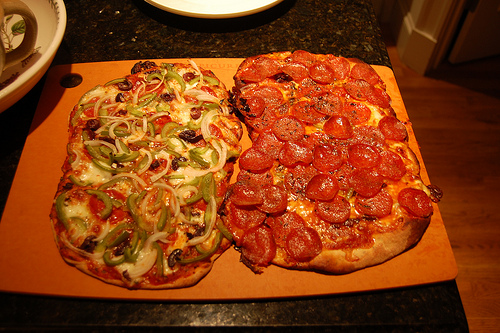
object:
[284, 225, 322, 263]
pepperoni slice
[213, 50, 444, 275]
pizza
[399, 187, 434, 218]
pepperoni slice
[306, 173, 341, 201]
pepperoni slice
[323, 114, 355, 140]
pepperoni slice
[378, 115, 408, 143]
pepperoni slice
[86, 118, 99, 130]
black olive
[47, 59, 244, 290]
pizza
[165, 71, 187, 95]
green pepper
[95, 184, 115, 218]
green pepper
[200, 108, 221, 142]
onion slice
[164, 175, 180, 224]
onion slice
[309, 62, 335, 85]
pepperoni slice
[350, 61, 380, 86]
pepperoni slice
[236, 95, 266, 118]
pepperoni slice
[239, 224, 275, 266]
pepperoni slice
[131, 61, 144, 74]
black olive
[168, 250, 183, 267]
black olive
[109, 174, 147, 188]
onion slice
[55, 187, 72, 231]
green pepper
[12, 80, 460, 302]
tray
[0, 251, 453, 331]
counter top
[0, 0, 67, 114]
bowl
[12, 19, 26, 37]
foliage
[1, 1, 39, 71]
cup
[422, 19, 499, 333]
floor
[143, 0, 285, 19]
plate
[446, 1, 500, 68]
door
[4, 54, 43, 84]
handle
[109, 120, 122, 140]
onion slice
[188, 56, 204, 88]
onion slice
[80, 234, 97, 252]
black olive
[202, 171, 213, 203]
green pepper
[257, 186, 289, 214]
pepperoni slice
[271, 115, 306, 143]
pepperoni slice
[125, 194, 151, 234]
green pepper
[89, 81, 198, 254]
toppings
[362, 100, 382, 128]
cheese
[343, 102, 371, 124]
pepperoni slice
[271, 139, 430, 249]
cheese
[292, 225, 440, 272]
crust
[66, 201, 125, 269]
cheese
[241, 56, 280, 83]
pepperoni slice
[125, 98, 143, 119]
green pepper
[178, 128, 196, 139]
black olive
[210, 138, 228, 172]
onion slice